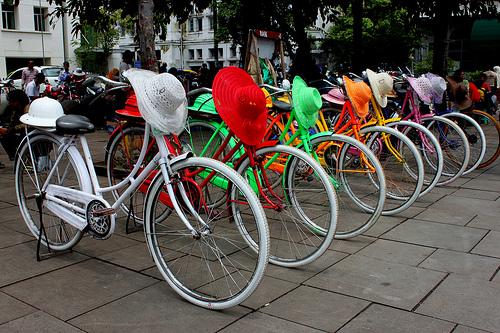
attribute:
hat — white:
[124, 64, 196, 131]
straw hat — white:
[123, 65, 190, 130]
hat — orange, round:
[339, 72, 371, 116]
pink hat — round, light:
[407, 72, 435, 103]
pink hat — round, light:
[320, 87, 347, 104]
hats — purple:
[401, 71, 446, 105]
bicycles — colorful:
[51, 69, 468, 288]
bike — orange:
[269, 82, 426, 218]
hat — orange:
[341, 72, 370, 123]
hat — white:
[12, 87, 77, 128]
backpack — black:
[484, 87, 494, 113]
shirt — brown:
[448, 83, 475, 106]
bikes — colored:
[94, 57, 464, 278]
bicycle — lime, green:
[166, 81, 387, 243]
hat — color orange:
[341, 76, 373, 123]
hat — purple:
[409, 73, 431, 104]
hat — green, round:
[284, 73, 332, 129]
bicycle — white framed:
[19, 75, 264, 267]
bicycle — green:
[192, 88, 387, 234]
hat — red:
[208, 66, 273, 148]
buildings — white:
[27, 1, 321, 68]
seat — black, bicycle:
[46, 114, 98, 139]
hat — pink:
[398, 65, 442, 107]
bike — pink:
[351, 67, 480, 193]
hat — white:
[117, 66, 194, 142]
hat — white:
[15, 90, 67, 130]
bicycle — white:
[6, 78, 274, 312]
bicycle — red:
[92, 80, 342, 278]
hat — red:
[113, 86, 142, 122]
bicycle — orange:
[245, 84, 435, 216]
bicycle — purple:
[385, 75, 475, 189]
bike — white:
[11, 86, 274, 313]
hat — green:
[289, 75, 326, 135]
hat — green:
[184, 89, 222, 114]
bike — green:
[161, 81, 390, 243]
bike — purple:
[388, 85, 481, 176]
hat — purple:
[419, 68, 450, 107]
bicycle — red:
[104, 101, 342, 269]